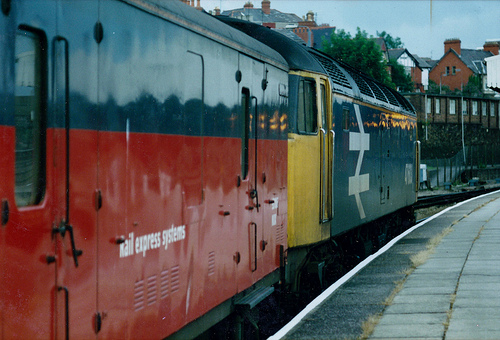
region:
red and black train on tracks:
[1, 3, 295, 339]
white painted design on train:
[333, 91, 383, 228]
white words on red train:
[103, 215, 198, 274]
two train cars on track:
[1, 3, 423, 338]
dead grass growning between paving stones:
[357, 208, 478, 338]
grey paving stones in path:
[363, 218, 495, 335]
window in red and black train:
[8, 12, 53, 220]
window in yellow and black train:
[293, 73, 326, 141]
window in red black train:
[226, 88, 264, 182]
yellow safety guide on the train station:
[360, 196, 499, 336]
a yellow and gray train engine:
[287, 20, 418, 248]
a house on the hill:
[420, 37, 498, 163]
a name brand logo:
[118, 224, 185, 257]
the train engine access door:
[0, 0, 70, 339]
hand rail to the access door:
[317, 125, 335, 225]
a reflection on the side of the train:
[363, 108, 418, 132]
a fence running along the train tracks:
[420, 158, 499, 190]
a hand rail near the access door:
[51, 30, 81, 272]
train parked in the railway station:
[78, 24, 423, 324]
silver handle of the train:
[318, 125, 340, 232]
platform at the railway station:
[387, 228, 475, 328]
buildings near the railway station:
[431, 43, 493, 128]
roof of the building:
[463, 45, 485, 67]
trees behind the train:
[336, 32, 388, 64]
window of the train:
[6, 25, 68, 220]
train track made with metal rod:
[436, 180, 456, 206]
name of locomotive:
[111, 215, 220, 267]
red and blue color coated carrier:
[76, 16, 273, 336]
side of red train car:
[93, 149, 204, 199]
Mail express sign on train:
[108, 217, 200, 259]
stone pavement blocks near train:
[393, 256, 469, 311]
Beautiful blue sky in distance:
[412, 18, 452, 36]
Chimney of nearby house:
[438, 36, 465, 49]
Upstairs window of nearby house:
[445, 64, 461, 79]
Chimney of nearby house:
[258, 0, 272, 10]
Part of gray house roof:
[458, 50, 476, 61]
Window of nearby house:
[446, 96, 459, 120]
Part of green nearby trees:
[378, 33, 400, 50]